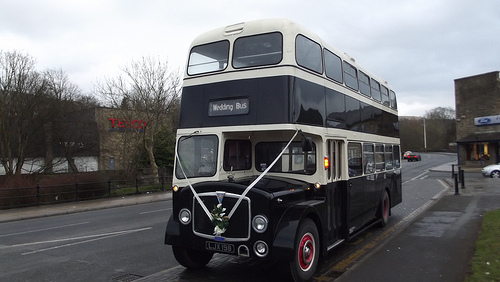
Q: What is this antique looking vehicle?
A: A bus.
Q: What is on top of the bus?
A: Second level.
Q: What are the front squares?
A: Windows.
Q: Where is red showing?
A: On tire.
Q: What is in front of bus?
A: Lights.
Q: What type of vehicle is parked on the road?
A: Bus.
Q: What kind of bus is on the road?
A: Double decker bus.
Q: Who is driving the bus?
A: Bus driver.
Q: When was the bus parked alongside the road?
A: During daylight hours.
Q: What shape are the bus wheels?
A: Round.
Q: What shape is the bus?
A: Rectangular.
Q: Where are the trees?
A: Along the side of the road.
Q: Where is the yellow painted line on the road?
A: Beside the sidewalk.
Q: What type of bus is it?
A: Double Decker.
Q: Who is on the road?
A: No one.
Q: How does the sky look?
A: Cloudy.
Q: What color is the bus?
A: Black and white.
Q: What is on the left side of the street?
A: Buildings.